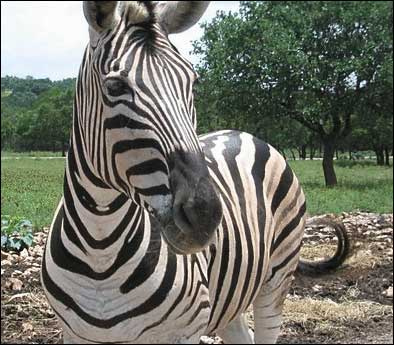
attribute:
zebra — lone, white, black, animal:
[52, 5, 327, 341]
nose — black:
[161, 146, 229, 241]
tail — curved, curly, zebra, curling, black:
[300, 212, 356, 280]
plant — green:
[0, 214, 37, 254]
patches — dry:
[288, 294, 393, 329]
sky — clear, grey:
[1, 3, 83, 73]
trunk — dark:
[316, 107, 353, 188]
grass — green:
[301, 155, 393, 209]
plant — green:
[257, 1, 389, 188]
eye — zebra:
[97, 75, 138, 103]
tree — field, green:
[219, 0, 393, 188]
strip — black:
[219, 128, 295, 225]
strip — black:
[214, 245, 271, 308]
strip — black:
[130, 27, 196, 156]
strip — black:
[120, 256, 190, 316]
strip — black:
[42, 209, 95, 284]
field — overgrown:
[2, 76, 67, 220]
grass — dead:
[309, 292, 377, 327]